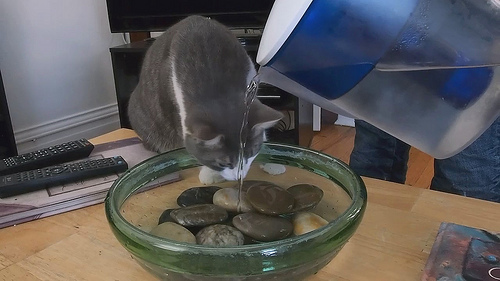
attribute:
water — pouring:
[211, 66, 271, 195]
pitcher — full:
[254, 0, 498, 160]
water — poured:
[235, 56, 497, 213]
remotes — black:
[4, 137, 127, 192]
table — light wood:
[368, 171, 449, 279]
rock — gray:
[209, 183, 254, 212]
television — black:
[106, 0, 276, 34]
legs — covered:
[346, 120, 497, 196]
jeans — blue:
[338, 102, 498, 201]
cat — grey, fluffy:
[124, 13, 261, 178]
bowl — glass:
[101, 140, 368, 273]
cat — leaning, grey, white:
[127, 15, 284, 182]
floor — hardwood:
[325, 125, 432, 180]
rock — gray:
[233, 210, 292, 237]